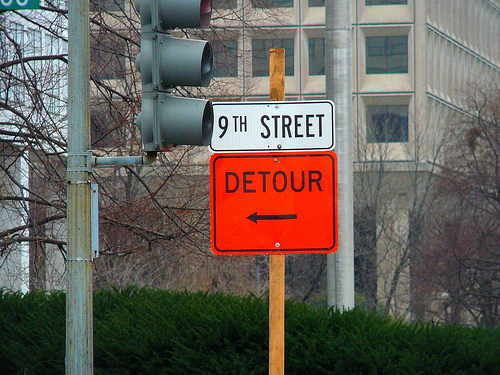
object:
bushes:
[0, 277, 500, 375]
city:
[0, 0, 500, 375]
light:
[132, 0, 214, 153]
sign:
[209, 99, 339, 155]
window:
[366, 104, 408, 143]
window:
[308, 38, 325, 74]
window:
[252, 39, 294, 76]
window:
[90, 35, 127, 78]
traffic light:
[135, 3, 223, 154]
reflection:
[365, 36, 405, 74]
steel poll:
[64, 0, 95, 375]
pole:
[267, 47, 284, 374]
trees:
[410, 89, 496, 331]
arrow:
[246, 211, 297, 225]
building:
[0, 0, 500, 321]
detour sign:
[209, 150, 339, 255]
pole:
[64, 1, 96, 375]